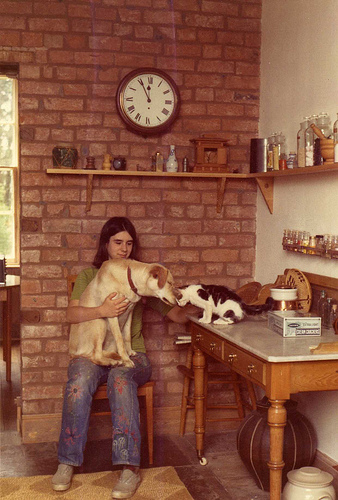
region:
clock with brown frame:
[115, 67, 181, 135]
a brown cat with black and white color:
[173, 283, 266, 325]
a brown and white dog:
[65, 257, 183, 368]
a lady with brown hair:
[91, 214, 137, 272]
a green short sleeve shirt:
[67, 266, 149, 353]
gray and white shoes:
[109, 468, 142, 498]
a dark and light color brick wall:
[0, 0, 263, 444]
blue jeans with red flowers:
[55, 351, 152, 468]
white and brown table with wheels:
[190, 310, 336, 498]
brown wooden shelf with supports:
[44, 162, 337, 216]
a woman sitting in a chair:
[50, 213, 153, 498]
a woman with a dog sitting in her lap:
[49, 216, 183, 499]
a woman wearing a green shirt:
[49, 214, 153, 498]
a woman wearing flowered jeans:
[49, 214, 155, 498]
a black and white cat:
[173, 279, 248, 326]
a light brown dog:
[67, 258, 182, 371]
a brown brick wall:
[20, 0, 255, 410]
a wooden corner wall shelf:
[45, 161, 337, 214]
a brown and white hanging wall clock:
[112, 63, 183, 139]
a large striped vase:
[233, 396, 322, 493]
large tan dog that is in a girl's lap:
[65, 259, 179, 369]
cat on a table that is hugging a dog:
[175, 281, 272, 326]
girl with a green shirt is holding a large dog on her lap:
[51, 215, 154, 496]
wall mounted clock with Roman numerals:
[113, 64, 184, 137]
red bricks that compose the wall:
[38, 32, 111, 137]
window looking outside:
[2, 68, 23, 265]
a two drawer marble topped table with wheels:
[186, 314, 337, 497]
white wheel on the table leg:
[195, 454, 209, 468]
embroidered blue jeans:
[57, 354, 149, 464]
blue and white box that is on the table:
[263, 307, 323, 338]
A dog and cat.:
[65, 254, 274, 367]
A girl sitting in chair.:
[41, 233, 145, 497]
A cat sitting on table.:
[174, 280, 279, 331]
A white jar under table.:
[280, 466, 334, 498]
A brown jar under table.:
[236, 388, 316, 491]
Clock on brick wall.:
[104, 59, 188, 141]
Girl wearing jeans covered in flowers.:
[48, 353, 153, 470]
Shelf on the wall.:
[44, 135, 263, 213]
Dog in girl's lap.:
[64, 253, 178, 373]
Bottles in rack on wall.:
[277, 222, 336, 264]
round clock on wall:
[113, 63, 177, 134]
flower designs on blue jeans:
[59, 365, 133, 461]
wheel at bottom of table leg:
[193, 449, 207, 465]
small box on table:
[262, 305, 322, 336]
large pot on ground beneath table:
[232, 388, 314, 486]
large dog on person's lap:
[66, 258, 174, 364]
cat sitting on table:
[175, 277, 241, 326]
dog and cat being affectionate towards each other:
[141, 258, 194, 307]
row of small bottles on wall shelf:
[276, 222, 333, 256]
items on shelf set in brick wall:
[39, 133, 251, 213]